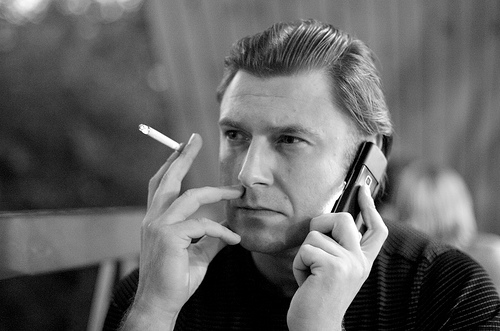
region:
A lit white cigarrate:
[133, 121, 193, 149]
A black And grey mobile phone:
[336, 139, 404, 219]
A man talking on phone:
[96, 22, 496, 327]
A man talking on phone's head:
[130, 25, 435, 221]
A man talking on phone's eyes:
[215, 119, 316, 147]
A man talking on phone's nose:
[229, 146, 283, 190]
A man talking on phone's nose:
[225, 199, 295, 221]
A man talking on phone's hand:
[115, 148, 232, 308]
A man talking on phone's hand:
[297, 216, 369, 329]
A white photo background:
[399, 36, 497, 169]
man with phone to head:
[113, 18, 498, 330]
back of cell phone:
[333, 140, 391, 229]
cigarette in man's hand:
[125, 118, 240, 329]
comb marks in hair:
[286, 21, 345, 68]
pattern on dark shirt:
[115, 219, 497, 328]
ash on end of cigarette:
[138, 122, 151, 136]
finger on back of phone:
[337, 140, 387, 248]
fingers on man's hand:
[144, 134, 244, 249]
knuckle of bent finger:
[310, 211, 358, 238]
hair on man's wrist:
[115, 292, 142, 329]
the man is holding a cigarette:
[55, 47, 215, 212]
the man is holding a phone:
[334, 138, 406, 275]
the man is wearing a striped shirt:
[389, 224, 445, 299]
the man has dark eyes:
[215, 113, 330, 165]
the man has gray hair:
[245, 27, 463, 142]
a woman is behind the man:
[396, 177, 478, 296]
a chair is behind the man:
[10, 193, 180, 320]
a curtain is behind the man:
[144, 11, 404, 259]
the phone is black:
[310, 128, 473, 309]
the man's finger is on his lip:
[195, 182, 312, 265]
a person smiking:
[79, 13, 499, 320]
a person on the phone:
[93, 15, 492, 324]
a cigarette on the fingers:
[136, 118, 183, 152]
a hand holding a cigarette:
[118, 117, 245, 329]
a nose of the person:
[234, 133, 277, 190]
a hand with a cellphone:
[281, 136, 394, 329]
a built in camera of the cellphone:
[363, 173, 375, 186]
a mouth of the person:
[233, 200, 287, 222]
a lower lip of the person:
[231, 208, 285, 220]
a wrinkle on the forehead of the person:
[228, 88, 295, 104]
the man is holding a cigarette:
[123, 13, 429, 320]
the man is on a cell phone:
[207, 9, 412, 296]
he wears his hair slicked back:
[212, 0, 409, 152]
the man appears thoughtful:
[141, 24, 453, 280]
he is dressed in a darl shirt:
[155, 220, 492, 328]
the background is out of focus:
[43, 15, 110, 250]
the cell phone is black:
[328, 128, 395, 222]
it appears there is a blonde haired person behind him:
[391, 155, 489, 273]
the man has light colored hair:
[215, 8, 407, 150]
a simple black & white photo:
[59, 8, 496, 325]